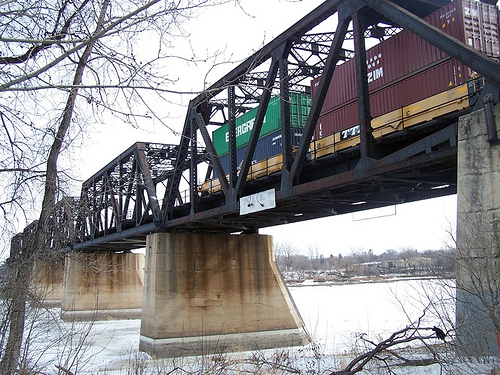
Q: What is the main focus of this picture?
A: A train on the bridge.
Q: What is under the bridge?
A: Water.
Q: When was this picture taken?
A: During daylight.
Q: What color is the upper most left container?
A: Green.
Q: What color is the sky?
A: White.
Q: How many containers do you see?
A: 4.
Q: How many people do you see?
A: 1.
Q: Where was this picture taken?
A: On a bridge.